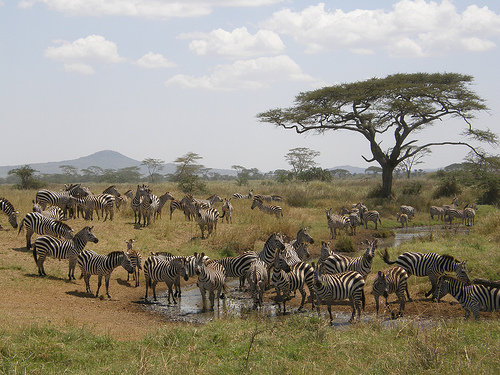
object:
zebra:
[141, 256, 189, 304]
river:
[153, 276, 466, 333]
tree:
[254, 70, 499, 196]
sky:
[1, 0, 498, 173]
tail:
[382, 248, 397, 265]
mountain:
[0, 150, 240, 176]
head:
[271, 232, 286, 250]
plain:
[0, 180, 500, 375]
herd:
[0, 183, 499, 326]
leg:
[298, 288, 306, 309]